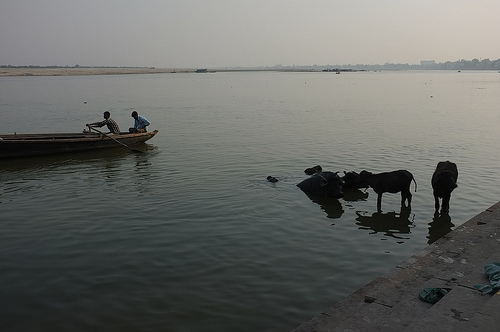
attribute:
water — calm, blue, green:
[4, 1, 500, 323]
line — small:
[3, 55, 500, 74]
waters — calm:
[5, 58, 500, 325]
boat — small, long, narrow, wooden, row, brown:
[1, 117, 162, 162]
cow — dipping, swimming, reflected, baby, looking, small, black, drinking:
[354, 164, 416, 221]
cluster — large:
[418, 252, 500, 309]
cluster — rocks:
[290, 198, 500, 329]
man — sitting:
[83, 110, 125, 139]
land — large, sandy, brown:
[1, 66, 204, 79]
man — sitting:
[128, 109, 153, 135]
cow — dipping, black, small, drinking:
[429, 158, 460, 218]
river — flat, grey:
[7, 70, 500, 323]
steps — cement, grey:
[300, 197, 500, 330]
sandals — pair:
[421, 280, 456, 303]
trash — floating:
[299, 161, 363, 201]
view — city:
[5, 40, 499, 97]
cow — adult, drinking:
[295, 168, 346, 203]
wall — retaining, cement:
[291, 198, 500, 330]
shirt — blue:
[131, 117, 152, 131]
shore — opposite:
[3, 63, 203, 79]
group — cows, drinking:
[293, 149, 462, 222]